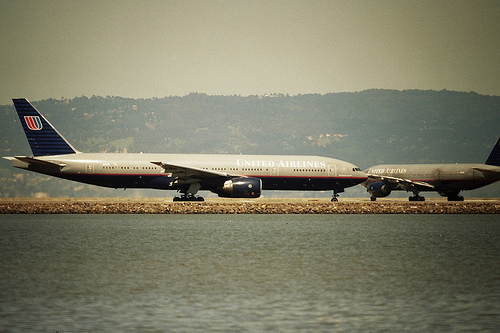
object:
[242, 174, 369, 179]
red stripe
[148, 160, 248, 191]
wing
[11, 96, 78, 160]
tail-fin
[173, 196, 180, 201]
wheel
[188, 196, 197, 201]
wheel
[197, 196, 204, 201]
wheel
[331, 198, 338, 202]
wheel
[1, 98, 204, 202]
rear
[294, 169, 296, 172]
windows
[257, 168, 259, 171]
windows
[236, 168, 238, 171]
windows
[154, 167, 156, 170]
windows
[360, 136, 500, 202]
airplane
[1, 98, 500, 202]
2 planes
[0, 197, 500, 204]
ground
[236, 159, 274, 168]
words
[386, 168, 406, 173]
words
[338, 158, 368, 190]
nose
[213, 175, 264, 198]
plane engine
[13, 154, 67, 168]
tail wing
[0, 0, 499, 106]
sky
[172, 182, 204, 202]
landing gear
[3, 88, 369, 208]
airplanes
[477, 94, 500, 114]
trees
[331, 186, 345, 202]
nose-gear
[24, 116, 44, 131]
logo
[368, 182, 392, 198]
engine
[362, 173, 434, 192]
left wing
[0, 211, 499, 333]
water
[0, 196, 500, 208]
airstrip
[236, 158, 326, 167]
white writing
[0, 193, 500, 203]
grass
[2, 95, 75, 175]
tail